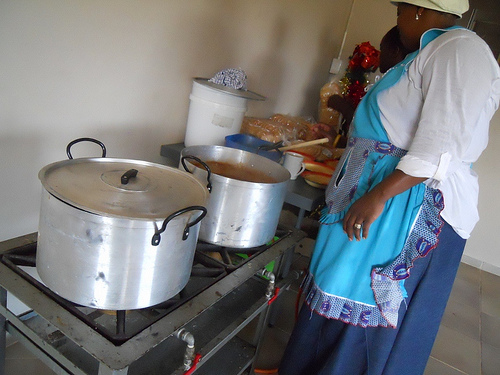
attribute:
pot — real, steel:
[36, 155, 211, 307]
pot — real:
[176, 147, 297, 250]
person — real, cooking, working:
[282, 2, 499, 374]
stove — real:
[0, 213, 305, 373]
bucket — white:
[185, 78, 246, 151]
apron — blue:
[301, 25, 442, 327]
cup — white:
[281, 152, 306, 181]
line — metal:
[176, 330, 202, 374]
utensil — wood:
[264, 136, 336, 154]